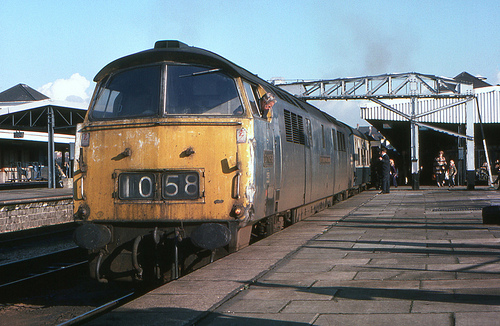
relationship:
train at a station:
[76, 34, 394, 214] [5, 65, 495, 320]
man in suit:
[376, 146, 392, 193] [379, 152, 391, 193]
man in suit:
[231, 91, 278, 122] [379, 152, 391, 193]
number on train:
[163, 172, 180, 197] [67, 38, 383, 287]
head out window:
[262, 93, 274, 108] [251, 80, 275, 117]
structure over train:
[265, 64, 496, 201] [62, 35, 402, 305]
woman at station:
[429, 146, 449, 186] [0, 81, 91, 210]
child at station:
[445, 155, 457, 186] [0, 81, 91, 210]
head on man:
[256, 89, 278, 111] [253, 91, 276, 119]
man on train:
[253, 91, 276, 119] [67, 38, 383, 287]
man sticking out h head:
[253, 91, 276, 119] [256, 89, 278, 111]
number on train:
[118, 175, 134, 195] [67, 38, 383, 287]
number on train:
[133, 172, 155, 197] [67, 38, 383, 287]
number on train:
[159, 170, 180, 197] [67, 38, 383, 287]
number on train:
[183, 172, 198, 194] [67, 38, 383, 287]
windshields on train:
[89, 60, 243, 116] [67, 38, 383, 287]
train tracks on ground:
[29, 245, 134, 324] [9, 238, 166, 324]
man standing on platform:
[376, 146, 392, 194] [79, 178, 484, 322]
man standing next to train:
[376, 146, 392, 194] [67, 38, 383, 287]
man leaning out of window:
[231, 91, 278, 122] [249, 82, 269, 119]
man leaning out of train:
[231, 91, 278, 122] [67, 38, 383, 287]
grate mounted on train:
[281, 102, 311, 149] [58, 23, 371, 292]